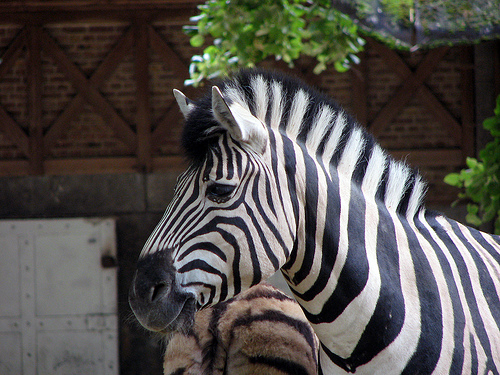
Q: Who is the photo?
A: Zebras.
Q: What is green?
A: Trees.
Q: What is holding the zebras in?
A: Gate.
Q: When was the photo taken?
A: Daytime.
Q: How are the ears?
A: Pointy.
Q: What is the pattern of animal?
A: Striped.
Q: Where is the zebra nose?
A: Above mouth.